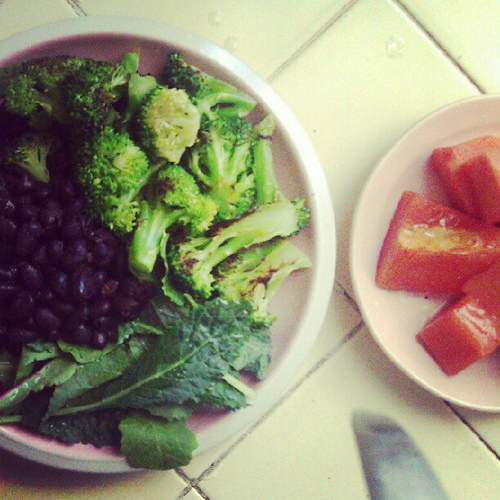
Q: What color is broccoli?
A: Green.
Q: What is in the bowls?
A: Broccoli, olives, lettuce, and tomatoes.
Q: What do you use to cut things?
A: A knife.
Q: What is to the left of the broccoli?
A: Olives.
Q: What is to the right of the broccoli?
A: Tomatoes.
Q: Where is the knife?
A: Below the tomatoes.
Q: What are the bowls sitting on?
A: Tiles.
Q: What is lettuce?
A: A plant.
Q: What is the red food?
A: Tomatoes.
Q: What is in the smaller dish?
A: Tomato.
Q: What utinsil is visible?
A: Knife.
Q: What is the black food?
A: Beans.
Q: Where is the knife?
A: On the tiled surface.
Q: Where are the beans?
A: In the larger bowl.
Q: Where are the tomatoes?
A: In the smaller bowl.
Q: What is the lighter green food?
A: Brocolli.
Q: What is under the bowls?
A: A tiled surface.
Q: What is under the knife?
A: A tiled surface.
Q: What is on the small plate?
A: Cut tomatoes.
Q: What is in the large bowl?
A: Broccoli lettuce and beans.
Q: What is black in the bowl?
A: Beans.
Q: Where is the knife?
A: Below the small plate.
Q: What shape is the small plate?
A: Round.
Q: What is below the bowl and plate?
A: Tile counter.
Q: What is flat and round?
A: Plate with tomatoes.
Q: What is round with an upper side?
A: Bowl with broccoli.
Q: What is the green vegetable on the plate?
A: Broccoli is green.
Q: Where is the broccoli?
A: On the plate.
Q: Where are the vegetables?
A: In a white bowl.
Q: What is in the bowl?
A: Vegetables.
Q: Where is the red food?
A: On the white plate.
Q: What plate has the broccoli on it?
A: The white bowl.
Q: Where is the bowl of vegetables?
A: On the table.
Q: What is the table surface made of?
A: Tiles.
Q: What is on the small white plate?
A: Tomato wedges.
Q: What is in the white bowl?
A: Broccoli pieces.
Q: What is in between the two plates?
A: Kitchen utensil.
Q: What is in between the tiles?
A: Grout.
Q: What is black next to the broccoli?
A: Beans.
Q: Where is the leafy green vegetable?
A: Next to the broccoli and beans.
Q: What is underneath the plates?
A: Tiles.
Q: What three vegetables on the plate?
A: Broccoli, beans and green vegetable.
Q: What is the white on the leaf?
A: Veins.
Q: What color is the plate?
A: White.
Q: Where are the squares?
A: Under the plates.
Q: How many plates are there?
A: Two.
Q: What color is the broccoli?
A: Green.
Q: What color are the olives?
A: Black.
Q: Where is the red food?
A: Right plate.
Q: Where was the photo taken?
A: Near food.